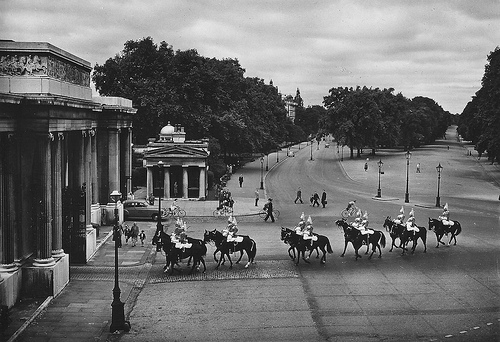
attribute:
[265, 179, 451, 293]
horses — walking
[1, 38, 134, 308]
building — big, large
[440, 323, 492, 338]
dashes — white, painted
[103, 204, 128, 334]
lamp post — black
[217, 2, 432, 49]
cloud — white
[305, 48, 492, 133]
cloud — white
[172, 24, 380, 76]
cloud — white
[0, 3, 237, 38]
cloud — white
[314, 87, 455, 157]
bushes — green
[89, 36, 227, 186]
tree — large, tall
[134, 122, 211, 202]
building —  top 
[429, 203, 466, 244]
horses — dark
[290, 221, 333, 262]
horses — dark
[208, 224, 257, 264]
horses — dark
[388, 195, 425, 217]
hats — pointed